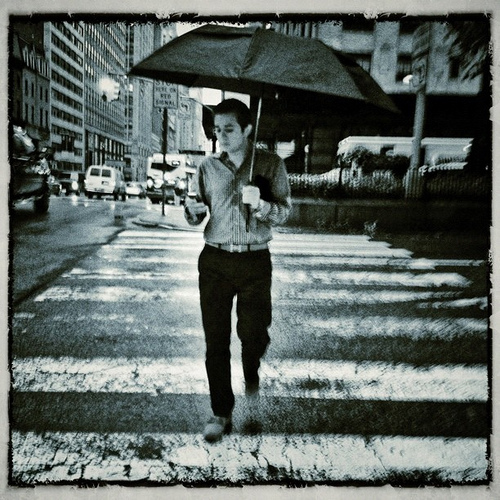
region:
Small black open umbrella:
[125, 20, 400, 116]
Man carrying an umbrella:
[130, 22, 395, 437]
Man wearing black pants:
[195, 241, 275, 408]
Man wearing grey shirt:
[186, 150, 291, 245]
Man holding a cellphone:
[183, 99, 290, 222]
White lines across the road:
[15, 224, 492, 495]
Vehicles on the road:
[13, 126, 192, 206]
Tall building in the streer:
[11, 19, 178, 179]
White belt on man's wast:
[197, 240, 277, 252]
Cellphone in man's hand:
[185, 185, 206, 215]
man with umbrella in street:
[102, 15, 390, 449]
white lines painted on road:
[325, 264, 479, 458]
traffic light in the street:
[89, 69, 136, 105]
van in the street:
[79, 159, 128, 201]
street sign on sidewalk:
[154, 104, 180, 222]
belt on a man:
[203, 232, 273, 266]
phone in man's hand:
[179, 183, 212, 219]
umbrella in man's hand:
[124, 18, 399, 121]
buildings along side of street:
[44, 29, 189, 156]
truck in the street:
[313, 128, 477, 196]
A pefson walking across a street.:
[177, 90, 297, 442]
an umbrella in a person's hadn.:
[131, 20, 392, 217]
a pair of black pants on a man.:
[194, 245, 276, 422]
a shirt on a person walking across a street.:
[184, 155, 303, 254]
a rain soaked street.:
[7, 229, 492, 497]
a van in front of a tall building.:
[77, 165, 141, 205]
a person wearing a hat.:
[194, 100, 269, 164]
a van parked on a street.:
[136, 156, 208, 203]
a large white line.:
[6, 352, 490, 404]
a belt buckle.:
[221, 236, 247, 258]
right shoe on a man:
[178, 407, 250, 456]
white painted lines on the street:
[315, 227, 475, 476]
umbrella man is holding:
[128, 11, 398, 127]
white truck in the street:
[315, 110, 481, 222]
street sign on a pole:
[145, 75, 187, 232]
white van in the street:
[76, 158, 133, 212]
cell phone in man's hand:
[177, 183, 212, 220]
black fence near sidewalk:
[286, 156, 479, 217]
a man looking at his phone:
[182, 99, 291, 443]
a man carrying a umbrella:
[124, 28, 399, 440]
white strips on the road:
[7, 361, 487, 478]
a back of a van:
[81, 166, 122, 198]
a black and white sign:
[154, 78, 178, 109]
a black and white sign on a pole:
[154, 79, 181, 220]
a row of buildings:
[14, 21, 198, 181]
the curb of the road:
[132, 216, 172, 230]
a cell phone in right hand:
[186, 189, 209, 219]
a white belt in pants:
[206, 238, 266, 255]